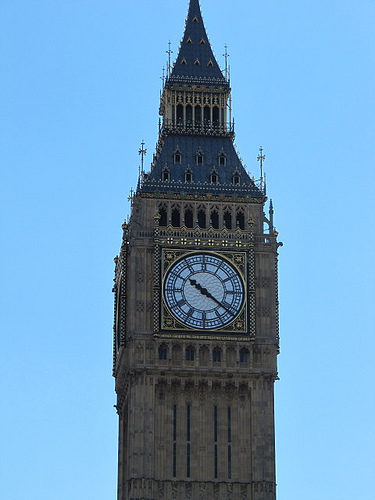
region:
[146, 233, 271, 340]
Clock on front of tower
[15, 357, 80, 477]
Blue sky with no clouds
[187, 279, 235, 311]
Hands on the clock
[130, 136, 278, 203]
Decorations on top of the steeple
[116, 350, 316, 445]
The steeple is made of stone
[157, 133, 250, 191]
Windows on top of tower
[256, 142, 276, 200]
Tall rod on building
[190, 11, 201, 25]
Window on very top of tower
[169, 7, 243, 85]
Tower steeple is blue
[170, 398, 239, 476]
Thin windows on side of building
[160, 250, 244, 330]
the face of a clock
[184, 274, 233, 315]
the hands of a clock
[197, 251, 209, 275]
a mark on the clock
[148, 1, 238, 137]
the top of the tower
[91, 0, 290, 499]
a large clock tower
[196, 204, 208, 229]
a window on the tower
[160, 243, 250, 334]
the frame of the clock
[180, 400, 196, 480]
a slit on the tower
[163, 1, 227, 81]
the roof of the tower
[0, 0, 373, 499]
a clear blue sky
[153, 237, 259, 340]
a big analog clock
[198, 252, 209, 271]
a notch on the clock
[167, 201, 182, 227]
a window on the tower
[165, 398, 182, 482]
a slit on the tower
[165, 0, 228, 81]
the roof on the tower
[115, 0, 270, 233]
the top of the tower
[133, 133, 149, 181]
ornamentation on the tower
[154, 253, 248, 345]
clock face on building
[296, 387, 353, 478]
blue sky over building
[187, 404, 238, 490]
windows on the building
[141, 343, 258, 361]
arched windows of the building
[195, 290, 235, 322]
minute hand of clock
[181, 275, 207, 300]
hour hand of clock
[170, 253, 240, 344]
clock telling the tme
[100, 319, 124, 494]
corner of the building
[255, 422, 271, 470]
bricks of the building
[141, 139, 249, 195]
roof of the building